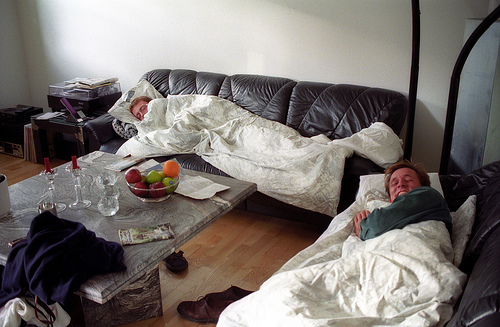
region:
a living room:
[8, 14, 483, 323]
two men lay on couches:
[43, 49, 485, 325]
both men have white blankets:
[85, 69, 472, 325]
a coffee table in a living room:
[14, 127, 254, 307]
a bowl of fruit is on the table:
[117, 153, 204, 222]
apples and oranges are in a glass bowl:
[122, 148, 207, 223]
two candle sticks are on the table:
[35, 146, 100, 218]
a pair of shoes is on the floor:
[177, 263, 283, 322]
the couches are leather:
[103, 53, 450, 234]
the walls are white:
[60, 2, 497, 117]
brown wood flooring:
[213, 235, 275, 260]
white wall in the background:
[126, 16, 257, 49]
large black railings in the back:
[435, 42, 498, 154]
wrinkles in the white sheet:
[329, 255, 444, 296]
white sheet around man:
[296, 243, 467, 313]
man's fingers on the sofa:
[342, 200, 395, 252]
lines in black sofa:
[238, 66, 365, 117]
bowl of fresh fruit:
[109, 146, 189, 212]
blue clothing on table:
[16, 205, 131, 287]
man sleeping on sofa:
[112, 72, 380, 206]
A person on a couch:
[81, 67, 339, 179]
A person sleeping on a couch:
[109, 87, 412, 205]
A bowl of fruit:
[109, 158, 207, 213]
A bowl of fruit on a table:
[102, 151, 294, 275]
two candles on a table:
[32, 149, 135, 249]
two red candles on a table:
[21, 147, 102, 225]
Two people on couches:
[86, 51, 461, 300]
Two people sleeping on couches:
[100, 78, 465, 317]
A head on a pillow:
[115, 76, 174, 144]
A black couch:
[97, 52, 429, 219]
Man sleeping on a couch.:
[91, 57, 383, 214]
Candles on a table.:
[22, 149, 130, 222]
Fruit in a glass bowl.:
[118, 152, 191, 206]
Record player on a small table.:
[38, 65, 125, 120]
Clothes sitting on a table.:
[0, 212, 192, 324]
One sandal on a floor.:
[158, 250, 205, 273]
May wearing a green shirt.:
[344, 160, 462, 264]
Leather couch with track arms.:
[101, 42, 421, 216]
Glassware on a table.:
[39, 172, 131, 222]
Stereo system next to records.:
[0, 104, 45, 158]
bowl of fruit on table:
[107, 154, 194, 207]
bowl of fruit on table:
[115, 153, 162, 199]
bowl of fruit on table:
[124, 165, 179, 204]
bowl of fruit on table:
[122, 144, 205, 237]